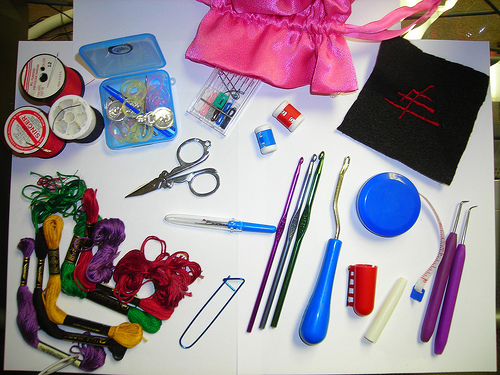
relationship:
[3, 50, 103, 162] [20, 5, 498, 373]
spools on table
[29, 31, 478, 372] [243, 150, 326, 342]
container has needles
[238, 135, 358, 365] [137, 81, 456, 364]
needles on table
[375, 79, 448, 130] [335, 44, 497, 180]
writing on cloth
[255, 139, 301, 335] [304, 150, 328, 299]
hooks next hooks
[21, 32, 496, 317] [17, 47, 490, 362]
table with craft supplies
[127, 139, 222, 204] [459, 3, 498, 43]
scissors on table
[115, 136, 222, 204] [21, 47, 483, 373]
metal scissors on table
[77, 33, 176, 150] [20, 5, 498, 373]
box on table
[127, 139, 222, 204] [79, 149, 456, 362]
scissors on table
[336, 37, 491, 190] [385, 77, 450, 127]
bag with japanese letters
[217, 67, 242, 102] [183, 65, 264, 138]
pin in box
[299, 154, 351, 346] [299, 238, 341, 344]
hook with handle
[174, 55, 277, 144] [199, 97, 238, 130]
case with needles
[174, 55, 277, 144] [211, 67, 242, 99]
case with pin